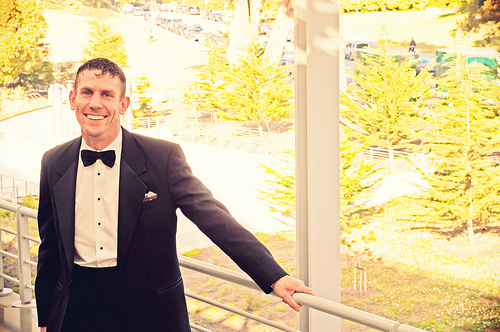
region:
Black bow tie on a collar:
[77, 148, 121, 168]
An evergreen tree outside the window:
[408, 53, 496, 253]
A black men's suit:
[36, 136, 287, 330]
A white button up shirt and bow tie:
[73, 134, 123, 266]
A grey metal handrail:
[0, 198, 499, 330]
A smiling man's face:
[67, 58, 129, 138]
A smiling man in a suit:
[33, 57, 313, 330]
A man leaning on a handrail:
[33, 57, 315, 330]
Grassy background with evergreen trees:
[1, 3, 497, 330]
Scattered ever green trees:
[1, 0, 498, 290]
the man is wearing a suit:
[26, 52, 224, 299]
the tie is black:
[75, 143, 132, 173]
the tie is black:
[78, 146, 118, 167]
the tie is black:
[66, 138, 143, 195]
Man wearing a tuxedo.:
[32, 55, 300, 330]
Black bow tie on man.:
[79, 143, 115, 171]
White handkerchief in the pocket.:
[140, 181, 160, 207]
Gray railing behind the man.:
[2, 192, 429, 330]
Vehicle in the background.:
[187, 3, 201, 18]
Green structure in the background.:
[435, 49, 498, 94]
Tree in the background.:
[396, 34, 498, 244]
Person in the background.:
[405, 35, 418, 54]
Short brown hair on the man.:
[63, 53, 131, 146]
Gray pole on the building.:
[287, 0, 345, 330]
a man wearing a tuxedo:
[28, 45, 347, 327]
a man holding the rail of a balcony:
[38, 60, 343, 319]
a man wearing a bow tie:
[63, 58, 133, 165]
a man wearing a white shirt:
[52, 55, 145, 274]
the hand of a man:
[271, 259, 314, 311]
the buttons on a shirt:
[91, 169, 107, 250]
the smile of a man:
[83, 111, 107, 123]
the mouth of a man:
[81, 110, 109, 122]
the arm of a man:
[161, 140, 288, 306]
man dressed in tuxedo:
[27, 52, 312, 330]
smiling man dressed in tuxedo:
[28, 54, 313, 330]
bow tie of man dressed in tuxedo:
[76, 144, 119, 166]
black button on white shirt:
[94, 168, 103, 177]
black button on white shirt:
[92, 191, 105, 205]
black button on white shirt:
[93, 217, 104, 229]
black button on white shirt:
[97, 242, 105, 252]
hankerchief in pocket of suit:
[139, 187, 158, 199]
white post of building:
[286, 3, 346, 330]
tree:
[418, 67, 496, 252]